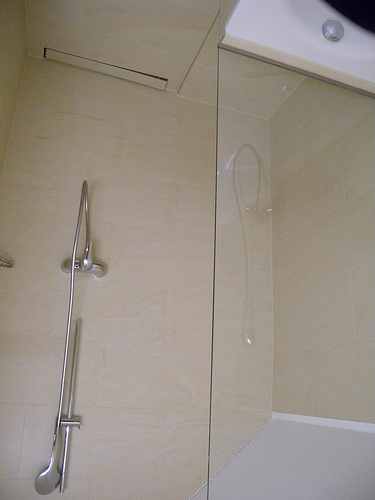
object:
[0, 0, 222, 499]
wall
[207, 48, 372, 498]
glass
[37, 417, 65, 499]
head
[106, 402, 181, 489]
tiles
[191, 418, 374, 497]
floor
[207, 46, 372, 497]
door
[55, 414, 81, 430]
metal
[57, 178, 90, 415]
hose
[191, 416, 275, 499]
line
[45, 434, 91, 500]
part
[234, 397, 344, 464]
part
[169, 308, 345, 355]
part